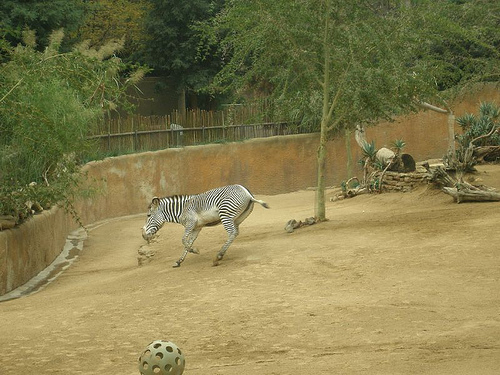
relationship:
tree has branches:
[189, 1, 442, 223] [298, 1, 356, 135]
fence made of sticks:
[67, 109, 328, 156] [147, 109, 220, 146]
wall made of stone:
[3, 82, 499, 299] [118, 169, 214, 189]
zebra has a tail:
[140, 184, 269, 267] [253, 198, 270, 210]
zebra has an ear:
[140, 184, 269, 267] [153, 196, 161, 208]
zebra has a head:
[140, 184, 269, 267] [142, 196, 166, 243]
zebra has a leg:
[140, 184, 269, 267] [217, 212, 239, 257]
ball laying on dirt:
[138, 339, 187, 374] [1, 159, 500, 374]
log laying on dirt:
[442, 182, 499, 205] [1, 159, 500, 374]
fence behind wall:
[67, 109, 328, 156] [3, 82, 499, 299]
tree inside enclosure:
[189, 1, 442, 223] [4, 2, 499, 374]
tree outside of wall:
[131, 0, 237, 112] [3, 82, 499, 299]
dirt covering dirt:
[1, 164, 499, 374] [1, 159, 500, 374]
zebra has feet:
[140, 184, 269, 267] [169, 248, 224, 269]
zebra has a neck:
[140, 184, 269, 267] [163, 193, 189, 224]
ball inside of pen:
[138, 339, 187, 374] [3, 84, 497, 374]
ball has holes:
[138, 339, 187, 374] [145, 350, 164, 363]